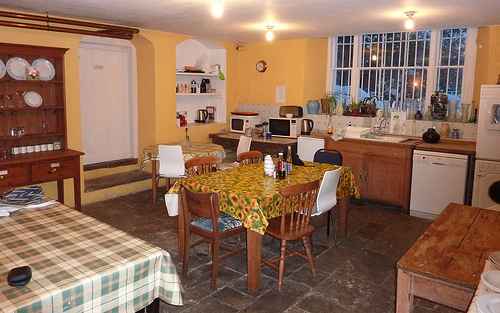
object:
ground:
[0, 163, 500, 313]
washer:
[406, 140, 474, 222]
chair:
[184, 157, 243, 255]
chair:
[237, 151, 264, 170]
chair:
[313, 148, 344, 248]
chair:
[260, 178, 322, 291]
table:
[163, 161, 361, 295]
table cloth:
[162, 158, 363, 237]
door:
[73, 34, 138, 168]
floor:
[60, 185, 462, 313]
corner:
[210, 38, 249, 132]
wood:
[430, 233, 472, 270]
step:
[79, 169, 156, 205]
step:
[81, 158, 137, 182]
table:
[393, 202, 499, 313]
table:
[139, 141, 225, 205]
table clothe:
[0, 201, 185, 313]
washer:
[471, 85, 500, 160]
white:
[426, 167, 457, 189]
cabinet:
[326, 133, 424, 215]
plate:
[31, 59, 56, 82]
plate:
[6, 56, 31, 81]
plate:
[0, 57, 7, 81]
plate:
[23, 91, 43, 107]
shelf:
[0, 42, 85, 210]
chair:
[177, 182, 245, 290]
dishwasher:
[409, 148, 471, 222]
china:
[0, 56, 56, 81]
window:
[324, 24, 479, 116]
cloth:
[163, 160, 362, 236]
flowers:
[222, 169, 263, 189]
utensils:
[0, 57, 57, 110]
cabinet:
[0, 43, 87, 212]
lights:
[201, 0, 441, 44]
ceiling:
[0, 0, 500, 42]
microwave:
[267, 117, 301, 138]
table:
[208, 131, 298, 157]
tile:
[336, 251, 396, 285]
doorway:
[0, 35, 146, 184]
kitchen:
[0, 0, 500, 313]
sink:
[351, 133, 410, 144]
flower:
[229, 194, 239, 206]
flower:
[250, 212, 261, 222]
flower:
[233, 210, 245, 222]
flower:
[200, 185, 209, 193]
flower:
[188, 180, 201, 191]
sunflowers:
[167, 159, 363, 236]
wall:
[0, 4, 234, 204]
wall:
[225, 19, 499, 143]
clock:
[256, 60, 269, 73]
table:
[0, 198, 184, 313]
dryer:
[469, 83, 499, 214]